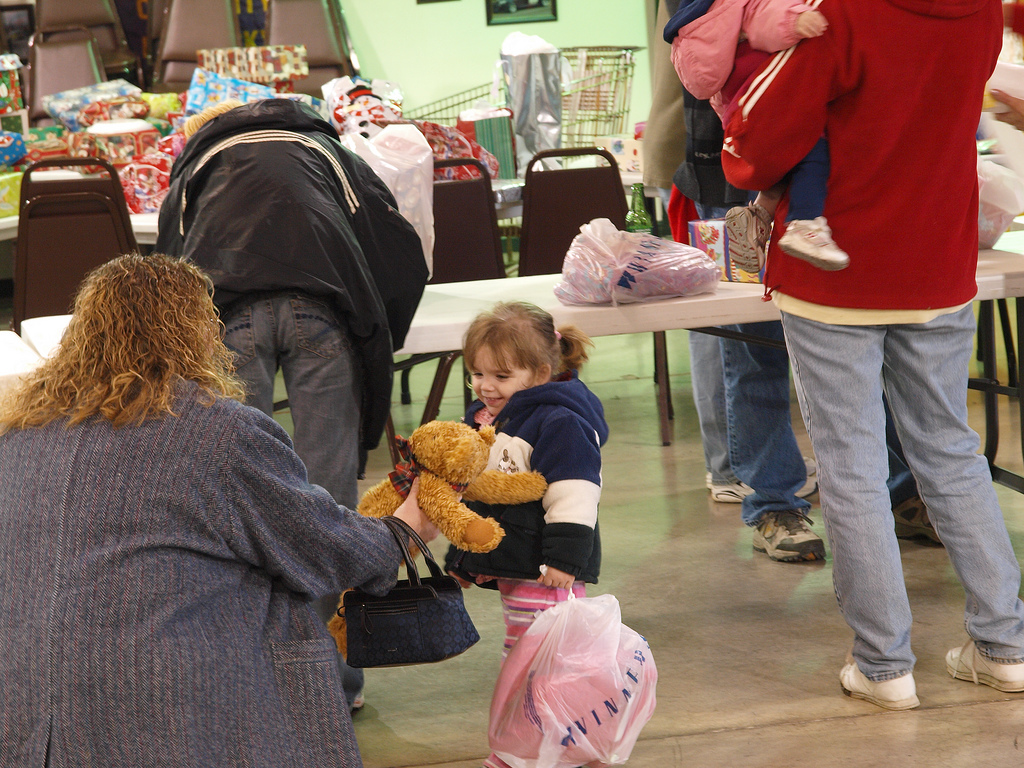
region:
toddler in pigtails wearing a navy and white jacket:
[462, 299, 592, 761]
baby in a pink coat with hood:
[661, 2, 826, 124]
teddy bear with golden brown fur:
[348, 406, 546, 546]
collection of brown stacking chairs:
[28, 2, 358, 89]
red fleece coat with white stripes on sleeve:
[729, 3, 1005, 326]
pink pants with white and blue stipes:
[490, 581, 585, 664]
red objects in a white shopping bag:
[496, 609, 661, 759]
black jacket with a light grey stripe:
[152, 94, 428, 465]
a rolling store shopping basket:
[395, 36, 646, 148]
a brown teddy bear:
[341, 372, 550, 598]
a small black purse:
[329, 495, 504, 680]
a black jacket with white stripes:
[103, 83, 437, 426]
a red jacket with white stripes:
[697, 10, 1011, 339]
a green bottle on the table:
[619, 174, 668, 247]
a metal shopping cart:
[416, 19, 648, 191]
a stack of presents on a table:
[0, 47, 405, 212]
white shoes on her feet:
[812, 632, 1022, 721]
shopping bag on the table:
[553, 203, 736, 308]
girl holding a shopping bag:
[470, 539, 661, 763]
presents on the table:
[2, 54, 507, 213]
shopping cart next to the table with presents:
[406, 30, 633, 175]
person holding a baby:
[652, 4, 1020, 297]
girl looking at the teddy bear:
[382, 274, 596, 556]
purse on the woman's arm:
[322, 492, 502, 680]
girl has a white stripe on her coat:
[499, 364, 617, 586]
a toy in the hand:
[293, 356, 579, 695]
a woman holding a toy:
[62, 233, 660, 750]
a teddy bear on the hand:
[191, 240, 660, 765]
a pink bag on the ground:
[472, 591, 785, 766]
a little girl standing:
[419, 247, 702, 750]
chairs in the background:
[22, 121, 934, 608]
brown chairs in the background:
[44, 54, 888, 539]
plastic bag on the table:
[501, 180, 816, 357]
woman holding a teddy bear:
[315, 376, 566, 615]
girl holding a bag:
[367, 265, 682, 765]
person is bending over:
[113, 72, 458, 440]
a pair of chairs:
[432, 141, 638, 269]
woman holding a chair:
[661, 4, 1007, 732]